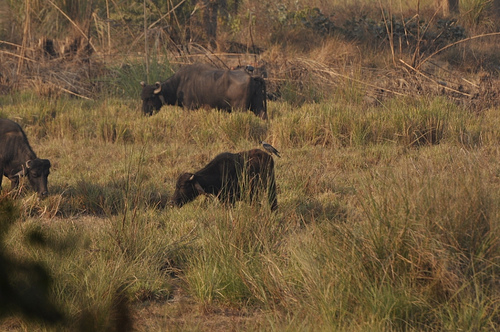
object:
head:
[140, 79, 166, 116]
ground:
[0, 69, 500, 332]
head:
[169, 172, 204, 210]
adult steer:
[167, 142, 281, 211]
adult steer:
[0, 111, 52, 199]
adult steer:
[139, 61, 268, 118]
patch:
[320, 140, 485, 222]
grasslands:
[1, 0, 500, 332]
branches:
[0, 2, 499, 97]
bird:
[259, 140, 282, 158]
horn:
[153, 81, 162, 94]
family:
[0, 64, 283, 204]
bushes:
[0, 0, 499, 66]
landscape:
[0, 0, 500, 332]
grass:
[0, 1, 499, 332]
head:
[18, 157, 51, 198]